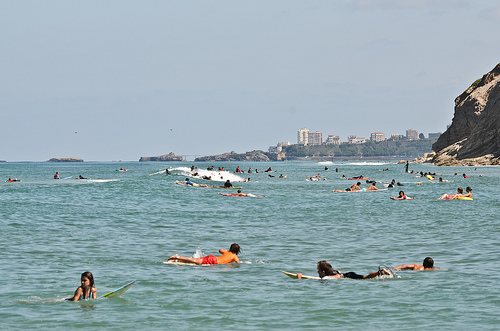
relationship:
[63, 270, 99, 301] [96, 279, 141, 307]
girl on top of surfboard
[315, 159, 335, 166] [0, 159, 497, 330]
wave in ocean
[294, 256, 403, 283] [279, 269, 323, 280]
guy on top of surfboard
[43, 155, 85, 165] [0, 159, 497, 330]
rock formation in ocean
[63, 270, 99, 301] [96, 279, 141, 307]
girl on surfboard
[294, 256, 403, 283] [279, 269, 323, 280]
guy holding surfboard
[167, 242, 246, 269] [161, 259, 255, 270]
boy on top of surfboard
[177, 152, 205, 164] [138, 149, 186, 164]
bridge to island